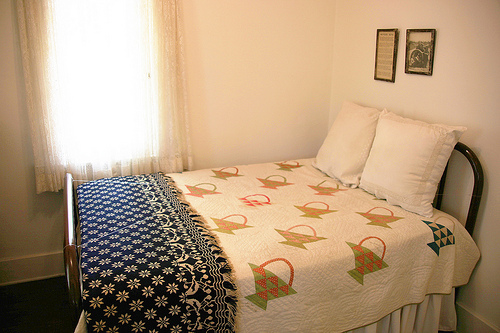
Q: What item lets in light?
A: A window.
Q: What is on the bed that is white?
A: Pillows.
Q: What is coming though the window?
A: Sun light.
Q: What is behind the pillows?
A: Head board.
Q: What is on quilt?
A: Baskets shapes.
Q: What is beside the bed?
A: A window.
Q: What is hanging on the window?
A: Curtains.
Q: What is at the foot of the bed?
A: A blue blanket.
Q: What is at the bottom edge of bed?
A: A ruffle.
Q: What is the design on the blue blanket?
A: White flowers.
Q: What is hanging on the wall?
A: A couple of pictures.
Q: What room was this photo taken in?
A: The bedroom.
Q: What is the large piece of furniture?
A: The bed.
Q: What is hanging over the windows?
A: Drapes.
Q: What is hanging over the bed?
A: Pictures.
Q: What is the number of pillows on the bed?
A: Two.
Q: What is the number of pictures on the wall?
A: Two.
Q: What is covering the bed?
A: A blanket.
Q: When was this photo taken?
A: In the daytime.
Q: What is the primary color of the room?
A: White.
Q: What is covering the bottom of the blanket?
A: Flowers.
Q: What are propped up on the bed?
A: Two pillows.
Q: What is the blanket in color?
A: White and blue.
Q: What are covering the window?
A: Curtains.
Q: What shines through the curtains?
A: Light.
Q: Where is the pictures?
A: Above the bed.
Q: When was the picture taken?
A: Daytime.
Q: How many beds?
A: One.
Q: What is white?
A: Pillow.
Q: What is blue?
A: Blanket.